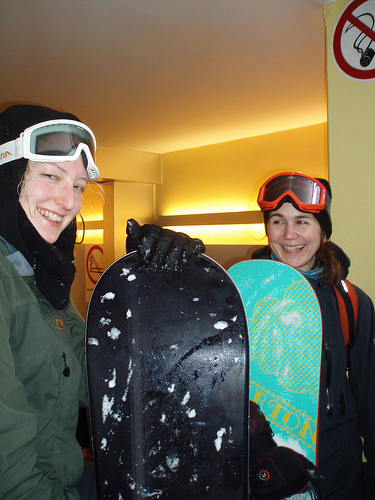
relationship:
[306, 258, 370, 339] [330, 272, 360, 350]
backpack has a strap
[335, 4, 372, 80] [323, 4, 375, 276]
sign posted on wall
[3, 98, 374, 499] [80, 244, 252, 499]
women holding snowboard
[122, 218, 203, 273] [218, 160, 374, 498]
gloves are on woman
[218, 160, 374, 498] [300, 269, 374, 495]
woman wearing skiing suit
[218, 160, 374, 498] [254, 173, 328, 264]
woman has a head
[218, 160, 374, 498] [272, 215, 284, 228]
woman has an eye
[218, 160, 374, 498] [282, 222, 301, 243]
woman has a nose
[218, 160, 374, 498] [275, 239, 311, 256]
woman has a mouth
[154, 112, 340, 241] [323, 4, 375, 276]
lights are mounted on wall